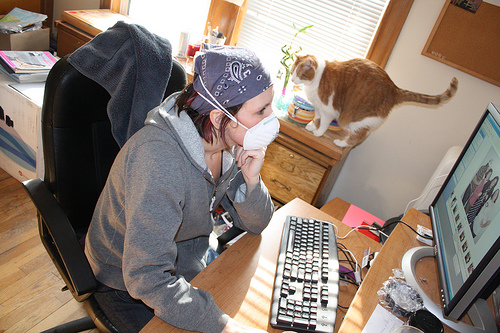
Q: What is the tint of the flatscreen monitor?
A: Silver and black.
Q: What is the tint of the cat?
A: Orange and white.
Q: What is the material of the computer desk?
A: Brown wood.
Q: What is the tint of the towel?
A: Grey.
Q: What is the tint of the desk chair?
A: Black.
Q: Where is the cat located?
A: On a side table.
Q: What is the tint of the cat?
A: Brown and white.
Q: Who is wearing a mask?
A: A woman.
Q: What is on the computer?
A: A screen.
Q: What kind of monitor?
A: Comptuer.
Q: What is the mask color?
A: White.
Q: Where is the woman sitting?
A: Desk.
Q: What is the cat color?
A: Brown.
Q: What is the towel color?
A: Blue.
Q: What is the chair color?
A: Black.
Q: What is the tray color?
A: Brown.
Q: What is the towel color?
A: Gray.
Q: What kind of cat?
A: Tabby.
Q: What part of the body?
A: Head.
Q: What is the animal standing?
A: Cat.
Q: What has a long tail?
A: Cat.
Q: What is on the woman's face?
A: Medical mask.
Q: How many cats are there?
A: One.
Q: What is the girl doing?
A: Looking at the computer.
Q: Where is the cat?
A: On top of the dresser.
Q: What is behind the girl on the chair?
A: A towel.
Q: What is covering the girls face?
A: A mask.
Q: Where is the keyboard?
A: In front of the girl.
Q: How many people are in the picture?
A: One.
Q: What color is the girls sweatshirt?
A: Gray.